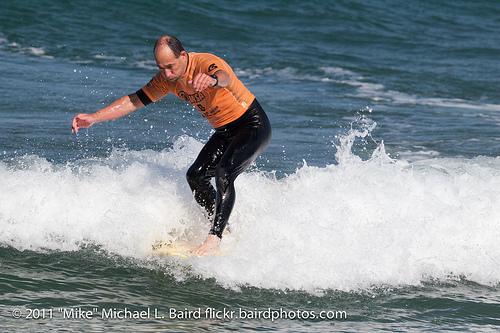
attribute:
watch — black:
[208, 72, 218, 85]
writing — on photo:
[13, 302, 354, 324]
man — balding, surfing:
[65, 23, 295, 268]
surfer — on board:
[52, 21, 302, 283]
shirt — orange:
[137, 51, 262, 133]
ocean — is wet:
[275, 30, 487, 157]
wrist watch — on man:
[209, 71, 219, 85]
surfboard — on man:
[149, 214, 204, 259]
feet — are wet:
[183, 230, 234, 263]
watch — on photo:
[208, 70, 221, 93]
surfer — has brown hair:
[147, 192, 301, 320]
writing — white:
[8, 304, 355, 324]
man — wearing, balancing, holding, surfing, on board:
[69, 35, 271, 255]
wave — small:
[311, 108, 457, 278]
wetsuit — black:
[187, 109, 274, 256]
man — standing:
[64, 28, 281, 262]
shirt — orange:
[90, 34, 264, 129]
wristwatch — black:
[210, 72, 217, 86]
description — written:
[11, 305, 348, 321]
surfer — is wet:
[69, 34, 271, 256]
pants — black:
[183, 98, 273, 239]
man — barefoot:
[101, 27, 329, 315]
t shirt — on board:
[132, 52, 262, 134]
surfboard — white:
[125, 214, 242, 282]